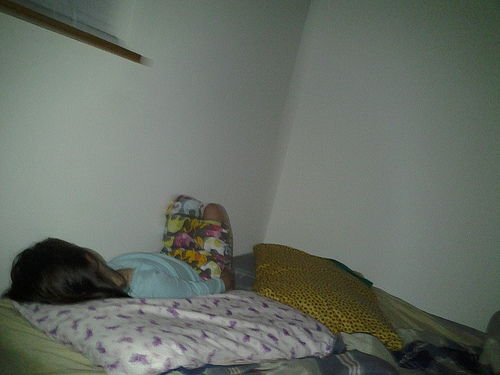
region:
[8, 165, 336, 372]
person lying on a bed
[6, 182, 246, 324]
person is sleeping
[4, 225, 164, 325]
person has black hair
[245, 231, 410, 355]
a yellow coushion on a bed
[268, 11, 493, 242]
wall of room is white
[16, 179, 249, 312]
person wears blue shirt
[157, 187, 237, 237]
knees are bend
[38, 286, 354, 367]
a white and purple comforter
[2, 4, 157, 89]
a window in the wall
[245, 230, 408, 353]
yellow pillow has black spots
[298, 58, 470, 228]
The color of the wall is white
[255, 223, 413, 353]
The pillow is the color yellow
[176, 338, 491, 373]
The blanket on the bed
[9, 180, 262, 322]
The girl is sleeping on the bed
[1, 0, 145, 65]
The window pain is the color brown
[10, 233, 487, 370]
The bed in the room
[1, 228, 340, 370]
The girl is laying on the pillow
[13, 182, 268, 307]
a person laying on a bed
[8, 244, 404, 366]
a bed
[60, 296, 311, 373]
a purple and white pillow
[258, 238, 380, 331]
a yellow pillow on the bed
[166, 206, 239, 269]
animal print on a skirt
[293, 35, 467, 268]
a white wall behind the bed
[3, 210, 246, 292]
a girl with long hair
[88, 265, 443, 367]
pillows on the bed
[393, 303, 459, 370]
a blanket on the bed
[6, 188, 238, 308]
a person laying on abed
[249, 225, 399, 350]
a pillow on a bed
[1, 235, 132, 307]
the head of a person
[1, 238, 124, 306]
a person with brown hair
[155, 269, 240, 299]
the arm of a person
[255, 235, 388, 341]
a yellow pillow with dots on it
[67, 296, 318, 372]
a purple pillow with darker purple print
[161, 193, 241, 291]
the bent legs of a person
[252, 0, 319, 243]
the corner of a room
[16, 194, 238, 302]
little kid lying in bed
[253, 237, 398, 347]
yellow pillow with black dots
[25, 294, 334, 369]
purple and white pillow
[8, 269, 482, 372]
yellow sheets on bed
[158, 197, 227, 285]
flowey pants of little girl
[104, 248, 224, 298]
light blue t-shirt of little girl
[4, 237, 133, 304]
dark and large hair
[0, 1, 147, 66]
brown wooden shelf on white wall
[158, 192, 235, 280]
two legs of little girl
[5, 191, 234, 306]
kid wearing light blue t-shirt and flowery pants